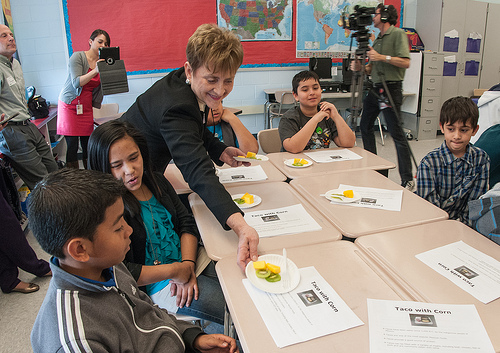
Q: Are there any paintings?
A: No, there are no paintings.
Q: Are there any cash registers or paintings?
A: No, there are no paintings or cash registers.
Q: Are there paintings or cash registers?
A: No, there are no paintings or cash registers.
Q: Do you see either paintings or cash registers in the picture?
A: No, there are no paintings or cash registers.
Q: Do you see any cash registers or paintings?
A: No, there are no paintings or cash registers.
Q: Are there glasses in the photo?
A: No, there are no glasses.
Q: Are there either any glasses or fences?
A: No, there are no glasses or fences.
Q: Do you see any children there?
A: Yes, there is a child.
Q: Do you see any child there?
A: Yes, there is a child.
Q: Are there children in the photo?
A: Yes, there is a child.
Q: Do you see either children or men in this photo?
A: Yes, there is a child.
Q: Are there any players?
A: No, there are no players.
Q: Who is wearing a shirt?
A: The child is wearing a shirt.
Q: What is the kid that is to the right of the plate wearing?
A: The kid is wearing a shirt.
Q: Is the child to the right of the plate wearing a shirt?
A: Yes, the child is wearing a shirt.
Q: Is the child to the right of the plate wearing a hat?
A: No, the kid is wearing a shirt.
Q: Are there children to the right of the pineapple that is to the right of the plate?
A: Yes, there is a child to the right of the pineapple.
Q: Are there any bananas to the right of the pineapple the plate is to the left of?
A: No, there is a child to the right of the pineapple.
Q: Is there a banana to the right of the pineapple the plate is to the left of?
A: No, there is a child to the right of the pineapple.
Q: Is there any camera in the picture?
A: Yes, there is a camera.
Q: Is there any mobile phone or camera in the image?
A: Yes, there is a camera.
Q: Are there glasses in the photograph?
A: No, there are no glasses.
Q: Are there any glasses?
A: No, there are no glasses.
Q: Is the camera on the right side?
A: Yes, the camera is on the right of the image.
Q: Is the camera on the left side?
A: No, the camera is on the right of the image.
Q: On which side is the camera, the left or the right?
A: The camera is on the right of the image.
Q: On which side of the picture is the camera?
A: The camera is on the right of the image.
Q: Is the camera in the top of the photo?
A: Yes, the camera is in the top of the image.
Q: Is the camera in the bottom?
A: No, the camera is in the top of the image.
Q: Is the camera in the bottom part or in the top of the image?
A: The camera is in the top of the image.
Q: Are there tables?
A: Yes, there is a table.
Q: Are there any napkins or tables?
A: Yes, there is a table.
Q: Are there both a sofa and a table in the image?
A: No, there is a table but no sofas.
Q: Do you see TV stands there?
A: No, there are no TV stands.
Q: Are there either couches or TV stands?
A: No, there are no TV stands or couches.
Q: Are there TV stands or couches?
A: No, there are no TV stands or couches.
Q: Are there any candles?
A: No, there are no candles.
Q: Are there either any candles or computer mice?
A: No, there are no candles or computer mice.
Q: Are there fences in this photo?
A: No, there are no fences.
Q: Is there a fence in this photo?
A: No, there are no fences.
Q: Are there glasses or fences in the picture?
A: No, there are no fences or glasses.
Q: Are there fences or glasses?
A: No, there are no fences or glasses.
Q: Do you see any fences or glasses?
A: No, there are no fences or glasses.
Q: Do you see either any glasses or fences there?
A: No, there are no fences or glasses.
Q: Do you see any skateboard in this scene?
A: No, there are no skateboards.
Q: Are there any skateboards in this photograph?
A: No, there are no skateboards.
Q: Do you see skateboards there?
A: No, there are no skateboards.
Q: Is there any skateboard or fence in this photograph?
A: No, there are no skateboards or fences.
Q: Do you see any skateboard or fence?
A: No, there are no skateboards or fences.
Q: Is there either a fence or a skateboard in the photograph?
A: No, there are no skateboards or fences.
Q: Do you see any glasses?
A: No, there are no glasses.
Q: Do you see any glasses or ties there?
A: No, there are no glasses or ties.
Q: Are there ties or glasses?
A: No, there are no glasses or ties.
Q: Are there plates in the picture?
A: Yes, there is a plate.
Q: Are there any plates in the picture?
A: Yes, there is a plate.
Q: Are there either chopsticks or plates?
A: Yes, there is a plate.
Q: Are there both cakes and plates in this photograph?
A: No, there is a plate but no cakes.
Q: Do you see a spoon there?
A: No, there are no spoons.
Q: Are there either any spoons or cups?
A: No, there are no spoons or cups.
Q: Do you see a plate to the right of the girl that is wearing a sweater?
A: Yes, there is a plate to the right of the girl.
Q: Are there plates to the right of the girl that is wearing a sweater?
A: Yes, there is a plate to the right of the girl.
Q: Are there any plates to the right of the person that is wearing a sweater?
A: Yes, there is a plate to the right of the girl.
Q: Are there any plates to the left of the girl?
A: No, the plate is to the right of the girl.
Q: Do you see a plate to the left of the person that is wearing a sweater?
A: No, the plate is to the right of the girl.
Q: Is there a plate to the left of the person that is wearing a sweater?
A: No, the plate is to the right of the girl.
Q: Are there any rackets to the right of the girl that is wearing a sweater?
A: No, there is a plate to the right of the girl.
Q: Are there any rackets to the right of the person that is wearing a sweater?
A: No, there is a plate to the right of the girl.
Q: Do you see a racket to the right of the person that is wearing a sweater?
A: No, there is a plate to the right of the girl.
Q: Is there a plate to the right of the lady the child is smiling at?
A: Yes, there is a plate to the right of the lady.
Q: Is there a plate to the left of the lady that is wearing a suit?
A: No, the plate is to the right of the lady.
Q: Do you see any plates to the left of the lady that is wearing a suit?
A: No, the plate is to the right of the lady.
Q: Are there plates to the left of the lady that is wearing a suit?
A: No, the plate is to the right of the lady.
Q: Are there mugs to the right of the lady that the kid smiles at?
A: No, there is a plate to the right of the lady.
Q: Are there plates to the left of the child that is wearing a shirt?
A: Yes, there is a plate to the left of the child.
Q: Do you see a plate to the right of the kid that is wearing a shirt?
A: No, the plate is to the left of the kid.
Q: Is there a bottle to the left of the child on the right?
A: No, there is a plate to the left of the kid.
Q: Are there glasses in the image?
A: No, there are no glasses.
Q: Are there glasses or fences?
A: No, there are no glasses or fences.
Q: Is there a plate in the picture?
A: Yes, there is a plate.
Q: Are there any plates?
A: Yes, there is a plate.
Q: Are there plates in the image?
A: Yes, there is a plate.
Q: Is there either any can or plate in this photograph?
A: Yes, there is a plate.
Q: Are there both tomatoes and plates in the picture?
A: No, there is a plate but no tomatoes.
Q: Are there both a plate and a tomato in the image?
A: No, there is a plate but no tomatoes.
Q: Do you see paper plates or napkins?
A: Yes, there is a paper plate.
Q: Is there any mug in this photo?
A: No, there are no mugs.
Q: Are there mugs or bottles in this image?
A: No, there are no mugs or bottles.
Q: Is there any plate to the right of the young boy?
A: Yes, there is a plate to the right of the boy.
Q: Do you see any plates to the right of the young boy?
A: Yes, there is a plate to the right of the boy.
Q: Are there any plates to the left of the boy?
A: No, the plate is to the right of the boy.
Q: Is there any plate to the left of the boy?
A: No, the plate is to the right of the boy.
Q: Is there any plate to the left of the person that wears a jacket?
A: No, the plate is to the right of the boy.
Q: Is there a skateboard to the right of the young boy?
A: No, there is a plate to the right of the boy.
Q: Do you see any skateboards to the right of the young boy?
A: No, there is a plate to the right of the boy.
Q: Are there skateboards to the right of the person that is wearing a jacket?
A: No, there is a plate to the right of the boy.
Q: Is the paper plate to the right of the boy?
A: Yes, the plate is to the right of the boy.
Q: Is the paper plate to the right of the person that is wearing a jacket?
A: Yes, the plate is to the right of the boy.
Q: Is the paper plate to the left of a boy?
A: No, the plate is to the right of a boy.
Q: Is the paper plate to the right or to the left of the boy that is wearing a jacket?
A: The plate is to the right of the boy.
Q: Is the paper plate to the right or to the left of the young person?
A: The plate is to the right of the boy.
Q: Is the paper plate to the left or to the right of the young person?
A: The plate is to the right of the boy.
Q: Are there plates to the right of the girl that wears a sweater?
A: Yes, there is a plate to the right of the girl.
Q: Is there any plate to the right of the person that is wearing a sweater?
A: Yes, there is a plate to the right of the girl.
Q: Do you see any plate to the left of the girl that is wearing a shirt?
A: No, the plate is to the right of the girl.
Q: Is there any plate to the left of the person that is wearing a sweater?
A: No, the plate is to the right of the girl.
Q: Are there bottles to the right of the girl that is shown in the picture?
A: No, there is a plate to the right of the girl.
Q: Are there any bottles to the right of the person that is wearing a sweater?
A: No, there is a plate to the right of the girl.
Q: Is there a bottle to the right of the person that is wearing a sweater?
A: No, there is a plate to the right of the girl.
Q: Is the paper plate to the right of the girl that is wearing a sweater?
A: Yes, the plate is to the right of the girl.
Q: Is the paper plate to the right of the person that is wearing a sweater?
A: Yes, the plate is to the right of the girl.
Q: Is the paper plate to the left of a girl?
A: No, the plate is to the right of a girl.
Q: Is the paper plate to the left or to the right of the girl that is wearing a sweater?
A: The plate is to the right of the girl.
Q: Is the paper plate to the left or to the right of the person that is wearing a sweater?
A: The plate is to the right of the girl.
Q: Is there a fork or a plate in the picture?
A: Yes, there is a plate.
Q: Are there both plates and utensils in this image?
A: No, there is a plate but no utensils.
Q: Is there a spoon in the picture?
A: No, there are no spoons.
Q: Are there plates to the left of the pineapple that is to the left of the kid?
A: Yes, there is a plate to the left of the pineapple.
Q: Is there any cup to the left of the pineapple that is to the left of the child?
A: No, there is a plate to the left of the pineapple.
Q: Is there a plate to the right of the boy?
A: Yes, there is a plate to the right of the boy.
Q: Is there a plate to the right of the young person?
A: Yes, there is a plate to the right of the boy.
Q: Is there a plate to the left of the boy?
A: No, the plate is to the right of the boy.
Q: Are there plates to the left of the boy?
A: No, the plate is to the right of the boy.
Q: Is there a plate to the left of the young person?
A: No, the plate is to the right of the boy.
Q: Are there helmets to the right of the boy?
A: No, there is a plate to the right of the boy.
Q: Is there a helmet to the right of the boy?
A: No, there is a plate to the right of the boy.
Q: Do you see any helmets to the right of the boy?
A: No, there is a plate to the right of the boy.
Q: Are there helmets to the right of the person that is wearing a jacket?
A: No, there is a plate to the right of the boy.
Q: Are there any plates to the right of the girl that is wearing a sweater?
A: Yes, there is a plate to the right of the girl.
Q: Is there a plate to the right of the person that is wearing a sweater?
A: Yes, there is a plate to the right of the girl.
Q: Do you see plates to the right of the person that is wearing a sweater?
A: Yes, there is a plate to the right of the girl.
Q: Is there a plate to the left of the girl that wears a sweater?
A: No, the plate is to the right of the girl.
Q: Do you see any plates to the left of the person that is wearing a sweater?
A: No, the plate is to the right of the girl.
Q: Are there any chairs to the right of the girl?
A: No, there is a plate to the right of the girl.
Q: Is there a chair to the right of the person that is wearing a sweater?
A: No, there is a plate to the right of the girl.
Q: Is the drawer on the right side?
A: Yes, the drawer is on the right of the image.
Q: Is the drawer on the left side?
A: No, the drawer is on the right of the image.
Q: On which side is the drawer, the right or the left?
A: The drawer is on the right of the image.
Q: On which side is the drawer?
A: The drawer is on the right of the image.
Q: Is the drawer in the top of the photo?
A: Yes, the drawer is in the top of the image.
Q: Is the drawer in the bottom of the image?
A: No, the drawer is in the top of the image.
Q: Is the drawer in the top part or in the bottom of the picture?
A: The drawer is in the top of the image.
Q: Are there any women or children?
A: Yes, there is a child.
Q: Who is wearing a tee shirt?
A: The kid is wearing a tee shirt.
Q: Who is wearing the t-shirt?
A: The kid is wearing a tee shirt.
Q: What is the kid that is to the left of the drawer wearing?
A: The kid is wearing a tee shirt.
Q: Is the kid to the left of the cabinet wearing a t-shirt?
A: Yes, the child is wearing a t-shirt.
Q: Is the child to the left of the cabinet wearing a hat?
A: No, the kid is wearing a t-shirt.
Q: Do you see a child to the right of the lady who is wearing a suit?
A: Yes, there is a child to the right of the lady.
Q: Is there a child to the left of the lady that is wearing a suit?
A: No, the child is to the right of the lady.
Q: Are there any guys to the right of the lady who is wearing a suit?
A: No, there is a child to the right of the lady.